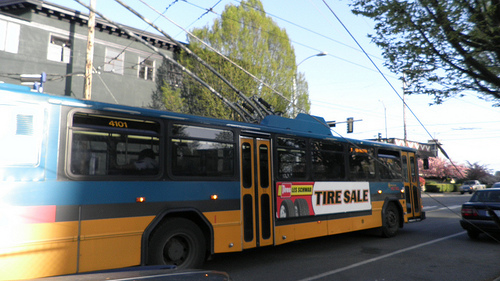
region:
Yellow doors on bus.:
[224, 113, 298, 268]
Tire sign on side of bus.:
[277, 175, 409, 244]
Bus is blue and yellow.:
[101, 135, 292, 267]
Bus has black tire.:
[158, 234, 208, 266]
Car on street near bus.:
[459, 190, 496, 221]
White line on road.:
[312, 242, 352, 269]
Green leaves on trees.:
[244, 40, 284, 95]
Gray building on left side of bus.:
[50, 48, 177, 130]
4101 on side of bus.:
[98, 107, 180, 159]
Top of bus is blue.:
[199, 105, 296, 122]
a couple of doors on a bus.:
[224, 127, 292, 252]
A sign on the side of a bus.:
[264, 164, 380, 236]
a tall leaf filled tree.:
[129, 0, 310, 130]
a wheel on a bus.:
[380, 197, 420, 237]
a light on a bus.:
[131, 190, 163, 207]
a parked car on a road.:
[449, 182, 499, 239]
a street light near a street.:
[289, 34, 340, 119]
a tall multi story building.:
[0, 0, 236, 82]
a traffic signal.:
[334, 102, 360, 139]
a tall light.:
[284, 45, 331, 119]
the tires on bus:
[127, 197, 240, 269]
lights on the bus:
[119, 185, 226, 210]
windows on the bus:
[77, 125, 223, 182]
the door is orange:
[237, 137, 274, 244]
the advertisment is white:
[270, 165, 383, 233]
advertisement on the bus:
[272, 178, 372, 226]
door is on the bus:
[235, 132, 279, 250]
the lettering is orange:
[102, 115, 129, 134]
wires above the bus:
[130, 15, 325, 175]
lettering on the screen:
[85, 115, 187, 144]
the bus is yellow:
[32, 99, 444, 271]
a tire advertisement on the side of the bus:
[243, 177, 365, 229]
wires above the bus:
[123, 0, 400, 67]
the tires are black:
[374, 190, 426, 241]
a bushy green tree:
[135, 0, 312, 117]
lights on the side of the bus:
[90, 187, 226, 214]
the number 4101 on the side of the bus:
[97, 104, 145, 134]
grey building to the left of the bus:
[0, 7, 156, 101]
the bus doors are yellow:
[208, 116, 280, 248]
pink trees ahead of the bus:
[402, 150, 467, 184]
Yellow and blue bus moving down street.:
[3, 80, 422, 272]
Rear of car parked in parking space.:
[456, 174, 498, 239]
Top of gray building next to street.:
[6, 5, 175, 108]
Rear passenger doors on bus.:
[233, 128, 284, 245]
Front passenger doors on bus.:
[393, 145, 428, 219]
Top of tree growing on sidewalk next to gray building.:
[153, 3, 310, 126]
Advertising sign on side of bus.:
[274, 178, 376, 224]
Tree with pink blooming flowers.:
[429, 153, 473, 190]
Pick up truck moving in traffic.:
[455, 176, 487, 198]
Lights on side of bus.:
[124, 186, 229, 204]